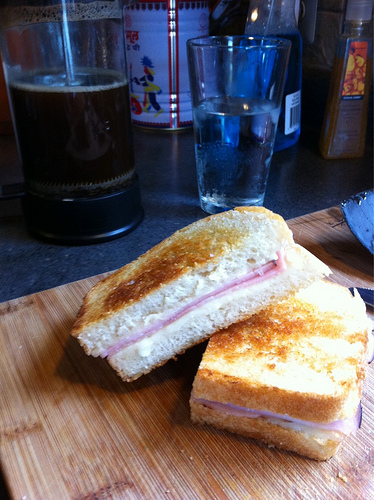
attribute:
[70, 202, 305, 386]
sandwich — toasted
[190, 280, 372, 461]
sandwich — toasted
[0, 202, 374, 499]
board — wooden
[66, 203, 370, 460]
sandwich — toasted, sliced